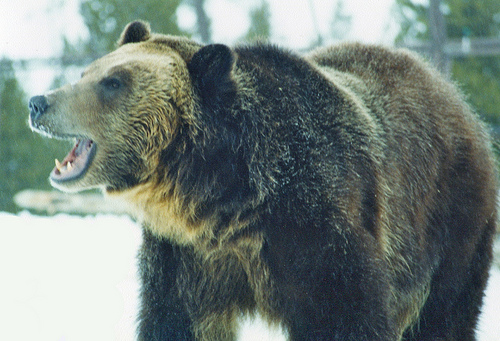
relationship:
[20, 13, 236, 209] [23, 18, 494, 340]
head on bear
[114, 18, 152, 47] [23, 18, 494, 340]
ear on bear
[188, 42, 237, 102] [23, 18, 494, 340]
ear on bear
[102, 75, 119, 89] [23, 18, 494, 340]
eye on bear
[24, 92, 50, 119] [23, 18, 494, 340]
nose on bear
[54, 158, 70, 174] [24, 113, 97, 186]
teeth in mouth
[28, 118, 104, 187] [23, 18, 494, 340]
mouth on bear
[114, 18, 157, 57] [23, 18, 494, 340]
ear on bear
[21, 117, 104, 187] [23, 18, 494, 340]
mouth on bear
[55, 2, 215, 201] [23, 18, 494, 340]
trees behind bear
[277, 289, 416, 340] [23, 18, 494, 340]
leg on bear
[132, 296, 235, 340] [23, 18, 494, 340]
leg on bear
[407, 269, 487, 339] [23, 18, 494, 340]
leg on bear